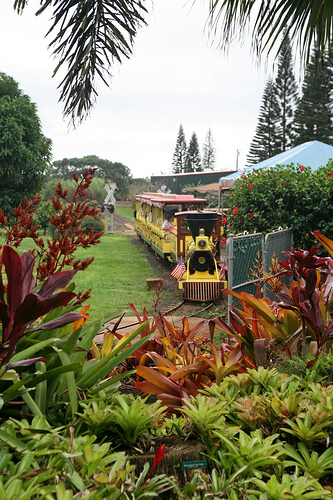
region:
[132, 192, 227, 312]
small yellow and red train for tourists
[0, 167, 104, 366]
tip of a burgundy plant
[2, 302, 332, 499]
plants around a tree stump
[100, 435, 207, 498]
tree stump in the middle of green and burgundy plants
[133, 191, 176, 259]
tourists on the right side of train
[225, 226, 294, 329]
two tall metal gates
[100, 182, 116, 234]
railroad crossing sign beside the tracks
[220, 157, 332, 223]
top of a tree with red flower blooms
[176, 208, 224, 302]
yellow and black front of train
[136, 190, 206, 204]
red roof on top of train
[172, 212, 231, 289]
engine of a small passenger train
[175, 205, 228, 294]
train is yellow and black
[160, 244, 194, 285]
american flag on train engine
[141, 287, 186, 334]
part of train track in front of train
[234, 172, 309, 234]
green bush with red flowers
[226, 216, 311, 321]
chain link gate near train tracks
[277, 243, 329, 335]
colorful plant behind gate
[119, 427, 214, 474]
tree stump surrounded by green plants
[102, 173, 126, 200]
white railroad crossing sign by train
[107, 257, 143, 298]
grass by tracks is green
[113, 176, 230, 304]
A little yellow train.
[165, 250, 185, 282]
The American flag hanging from the train.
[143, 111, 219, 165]
Green trees in the distance.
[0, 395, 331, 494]
Little green plants in the foreground.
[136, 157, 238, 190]
A building in the distance.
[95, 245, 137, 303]
The grass is green.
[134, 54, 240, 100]
The sky is overcast.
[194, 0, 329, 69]
A palm frond hanging down.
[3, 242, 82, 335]
Red leaves on a plant.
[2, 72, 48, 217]
A green tree in the background.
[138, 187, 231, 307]
red and yellow train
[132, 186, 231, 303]
train moving towards camera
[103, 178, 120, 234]
railroad crossing sign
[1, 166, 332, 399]
red and orange leaves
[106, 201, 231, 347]
brown metal tracks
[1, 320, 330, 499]
lush green plants in foreground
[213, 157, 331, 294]
large rosebush behind the fence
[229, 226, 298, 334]
chain-link fence separates plants from tracks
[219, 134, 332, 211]
light blue awning behind rosebush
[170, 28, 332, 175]
evergreen trees in background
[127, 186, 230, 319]
the train is yellow.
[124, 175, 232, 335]
the train is on a track.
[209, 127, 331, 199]
the tent is green.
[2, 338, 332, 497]
the plants are green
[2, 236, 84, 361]
the plant is purple.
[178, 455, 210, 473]
the sign is green.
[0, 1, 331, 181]
the sky is white.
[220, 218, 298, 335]
the fence is metal.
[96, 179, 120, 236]
the train sign is white and black.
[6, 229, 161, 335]
the grass is green.